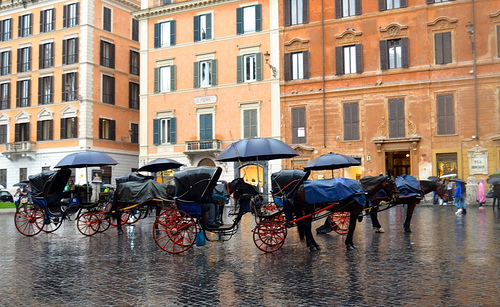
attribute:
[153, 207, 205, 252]
wheels — red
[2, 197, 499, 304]
street — wet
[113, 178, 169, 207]
raincoat — black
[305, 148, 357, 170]
umbrella — black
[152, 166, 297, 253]
carriage — horse drawn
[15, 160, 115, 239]
carriage — horse drawn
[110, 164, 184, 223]
carriage — horse drawn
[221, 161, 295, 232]
carriage — horse drawn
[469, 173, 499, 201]
raincoat — pink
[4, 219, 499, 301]
road — rainy, wet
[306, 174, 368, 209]
jacket — blue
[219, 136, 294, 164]
umbrella — big, black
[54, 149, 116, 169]
umbrella — big, black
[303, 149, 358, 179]
umbrella — big, black